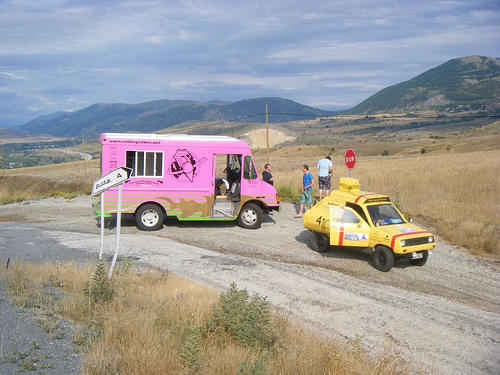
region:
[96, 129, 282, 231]
Pink research truck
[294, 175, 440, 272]
Yellow modified car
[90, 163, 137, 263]
White sign indicating distance to city in foreign language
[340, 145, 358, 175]
Red stop sign in foreign language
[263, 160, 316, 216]
Two men talking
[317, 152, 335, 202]
Man looking down at an object he is holding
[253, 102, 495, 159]
Power line and pole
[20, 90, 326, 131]
Mountain range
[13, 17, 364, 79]
Blue sky with with numerous white clouds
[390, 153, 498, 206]
Very dry grass field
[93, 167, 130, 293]
white and black street sign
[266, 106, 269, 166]
brown wooden electric pole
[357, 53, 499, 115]
grass covered mountain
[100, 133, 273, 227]
pink ice cream truck van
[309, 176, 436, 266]
yellow delivery car on street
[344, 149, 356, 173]
red octagon stop sign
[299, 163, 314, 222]
man standing on road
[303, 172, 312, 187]
aqua blue tee shirt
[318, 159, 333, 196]
man standing at side of rode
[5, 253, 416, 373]
dried grass next to road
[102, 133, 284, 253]
Pink truck with flame design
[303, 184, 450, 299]
Yellow car with red stripes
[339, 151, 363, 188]
Stop sign is red and white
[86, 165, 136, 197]
White and black directional sign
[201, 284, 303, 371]
Green shrub in the dead grass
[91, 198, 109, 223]
Green bumper on pink truck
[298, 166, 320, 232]
Man in blue shirt and green shorts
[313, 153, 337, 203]
Man in light blue shirt and plaid shorts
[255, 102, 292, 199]
Telephone pole for holding wires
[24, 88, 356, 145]
Beautiful moutain peaks in the distance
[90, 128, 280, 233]
the truck is pink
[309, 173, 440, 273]
the car is yellow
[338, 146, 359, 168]
the sign is red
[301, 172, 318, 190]
the shirt is blue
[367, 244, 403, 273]
the tire is black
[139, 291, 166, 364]
the grass is brown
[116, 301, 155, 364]
the grass is long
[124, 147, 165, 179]
window is on the truck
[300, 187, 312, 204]
the shorts are long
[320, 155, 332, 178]
the shirt is light blue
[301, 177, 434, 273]
a small yellow car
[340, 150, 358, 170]
a bright red stop sign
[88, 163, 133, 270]
bent white and black road sign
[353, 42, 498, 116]
mountain and sky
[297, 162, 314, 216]
young man in a blue shirt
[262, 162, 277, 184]
torso of a man in black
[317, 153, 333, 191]
backside of a man in a white shirt and shorts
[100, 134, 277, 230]
pink, green, and brown food truck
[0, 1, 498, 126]
mountainous terrain and cloudy sky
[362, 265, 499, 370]
gravel road